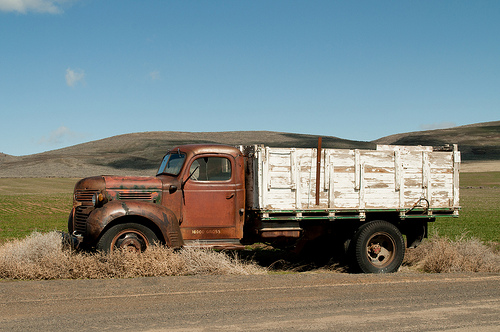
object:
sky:
[164, 35, 415, 105]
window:
[155, 152, 185, 175]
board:
[324, 149, 332, 190]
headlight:
[78, 191, 107, 206]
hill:
[4, 126, 499, 177]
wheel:
[98, 221, 162, 253]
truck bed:
[232, 142, 461, 222]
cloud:
[58, 54, 89, 94]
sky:
[1, 1, 496, 156]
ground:
[396, 84, 441, 127]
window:
[189, 154, 235, 185]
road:
[267, 269, 320, 296]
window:
[205, 161, 232, 182]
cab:
[63, 143, 247, 255]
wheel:
[348, 219, 406, 274]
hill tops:
[46, 73, 498, 176]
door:
[178, 149, 238, 236]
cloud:
[2, 0, 67, 18]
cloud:
[59, 63, 84, 87]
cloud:
[146, 65, 166, 86]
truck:
[233, 135, 462, 238]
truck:
[67, 137, 463, 274]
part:
[393, 237, 403, 250]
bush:
[0, 227, 270, 278]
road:
[0, 270, 499, 330]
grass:
[3, 233, 498, 274]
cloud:
[36, 121, 82, 151]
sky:
[251, 39, 408, 101]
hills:
[24, 115, 495, 175]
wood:
[300, 155, 414, 203]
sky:
[145, 27, 405, 107]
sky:
[210, 23, 401, 113]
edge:
[345, 247, 360, 271]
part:
[185, 155, 243, 211]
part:
[189, 160, 229, 189]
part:
[166, 158, 186, 178]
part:
[368, 249, 384, 257]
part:
[370, 238, 410, 278]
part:
[283, 273, 388, 329]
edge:
[85, 283, 225, 291]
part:
[35, 239, 55, 260]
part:
[198, 159, 245, 191]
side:
[86, 188, 409, 218]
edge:
[72, 140, 114, 171]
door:
[179, 146, 246, 239]